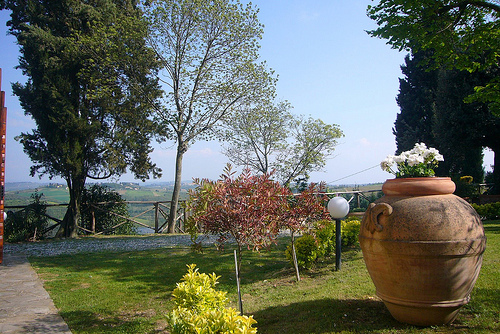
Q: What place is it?
A: It is a garden.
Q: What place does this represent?
A: It represents the garden.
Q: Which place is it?
A: It is a garden.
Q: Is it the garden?
A: Yes, it is the garden.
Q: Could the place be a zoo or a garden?
A: It is a garden.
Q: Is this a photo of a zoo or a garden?
A: It is showing a garden.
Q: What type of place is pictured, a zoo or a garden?
A: It is a garden.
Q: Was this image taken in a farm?
A: No, the picture was taken in a garden.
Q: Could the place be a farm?
A: No, it is a garden.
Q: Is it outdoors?
A: Yes, it is outdoors.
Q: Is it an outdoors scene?
A: Yes, it is outdoors.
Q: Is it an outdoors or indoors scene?
A: It is outdoors.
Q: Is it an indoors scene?
A: No, it is outdoors.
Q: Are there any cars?
A: No, there are no cars.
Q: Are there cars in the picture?
A: No, there are no cars.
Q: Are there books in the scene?
A: No, there are no books.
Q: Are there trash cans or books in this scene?
A: No, there are no books or trash cans.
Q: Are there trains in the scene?
A: No, there are no trains.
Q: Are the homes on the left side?
A: Yes, the homes are on the left of the image.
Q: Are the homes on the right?
A: No, the homes are on the left of the image.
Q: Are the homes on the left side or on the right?
A: The homes are on the left of the image.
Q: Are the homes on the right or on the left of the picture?
A: The homes are on the left of the image.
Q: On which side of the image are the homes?
A: The homes are on the left of the image.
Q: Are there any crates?
A: No, there are no crates.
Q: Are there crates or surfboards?
A: No, there are no crates or surfboards.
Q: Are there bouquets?
A: No, there are no bouquets.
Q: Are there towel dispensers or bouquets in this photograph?
A: No, there are no bouquets or towel dispensers.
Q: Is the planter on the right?
A: Yes, the planter is on the right of the image.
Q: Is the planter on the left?
A: No, the planter is on the right of the image.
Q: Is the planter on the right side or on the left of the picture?
A: The planter is on the right of the image.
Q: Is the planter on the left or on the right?
A: The planter is on the right of the image.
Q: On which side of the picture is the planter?
A: The planter is on the right of the image.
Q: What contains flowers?
A: The planter contains flowers.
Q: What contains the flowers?
A: The planter contains flowers.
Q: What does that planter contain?
A: The planter contains flowers.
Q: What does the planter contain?
A: The planter contains flowers.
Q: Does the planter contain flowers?
A: Yes, the planter contains flowers.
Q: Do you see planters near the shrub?
A: Yes, there is a planter near the shrub.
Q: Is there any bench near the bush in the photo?
A: No, there is a planter near the bush.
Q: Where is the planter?
A: The planter is in the garden.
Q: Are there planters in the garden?
A: Yes, there is a planter in the garden.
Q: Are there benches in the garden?
A: No, there is a planter in the garden.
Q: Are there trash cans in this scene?
A: No, there are no trash cans.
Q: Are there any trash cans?
A: No, there are no trash cans.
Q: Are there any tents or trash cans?
A: No, there are no trash cans or tents.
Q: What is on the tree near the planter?
A: The leaves are on the tree.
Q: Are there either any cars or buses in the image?
A: No, there are no cars or buses.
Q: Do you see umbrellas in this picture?
A: No, there are no umbrellas.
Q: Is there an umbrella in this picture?
A: No, there are no umbrellas.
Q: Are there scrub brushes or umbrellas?
A: No, there are no umbrellas or scrub brushes.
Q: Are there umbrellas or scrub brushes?
A: No, there are no umbrellas or scrub brushes.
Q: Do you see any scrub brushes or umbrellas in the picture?
A: No, there are no umbrellas or scrub brushes.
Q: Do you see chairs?
A: No, there are no chairs.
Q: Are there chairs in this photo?
A: No, there are no chairs.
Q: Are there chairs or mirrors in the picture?
A: No, there are no chairs or mirrors.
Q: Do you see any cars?
A: No, there are no cars.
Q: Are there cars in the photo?
A: No, there are no cars.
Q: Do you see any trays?
A: No, there are no trays.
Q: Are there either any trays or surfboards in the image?
A: No, there are no trays or surfboards.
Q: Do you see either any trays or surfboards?
A: No, there are no trays or surfboards.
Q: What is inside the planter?
A: The flowers are inside the planter.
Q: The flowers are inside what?
A: The flowers are inside the planter.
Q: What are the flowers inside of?
A: The flowers are inside the planter.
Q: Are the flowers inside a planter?
A: Yes, the flowers are inside a planter.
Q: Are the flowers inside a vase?
A: No, the flowers are inside a planter.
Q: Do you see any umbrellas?
A: No, there are no umbrellas.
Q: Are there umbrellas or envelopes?
A: No, there are no umbrellas or envelopes.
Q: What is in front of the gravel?
A: The garden is in front of the gravel.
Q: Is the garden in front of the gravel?
A: Yes, the garden is in front of the gravel.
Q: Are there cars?
A: No, there are no cars.